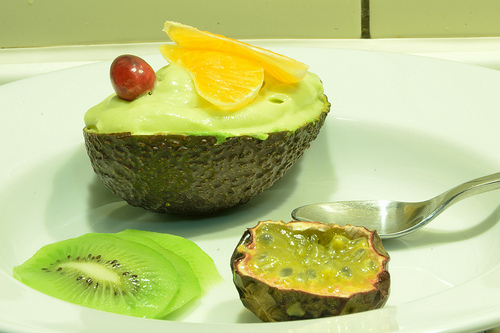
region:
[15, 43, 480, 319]
fruits arranged in a plate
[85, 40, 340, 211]
avocado half topped with fruit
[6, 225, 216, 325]
slices of overlapping kiwi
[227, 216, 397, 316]
cut fruit with thick skin and gooey interior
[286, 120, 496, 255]
silver spoon placed in a plate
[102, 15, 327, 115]
grape and orange segments on filled avocado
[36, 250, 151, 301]
black seeds in an oval shape around white center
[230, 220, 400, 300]
dark seeds in juicy opaque filling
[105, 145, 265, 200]
bumpy texture of avocado peel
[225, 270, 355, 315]
mottled skin covering fruit in earthy tones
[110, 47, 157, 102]
a single olive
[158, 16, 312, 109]
two orange slices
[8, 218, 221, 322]
three kiwi slices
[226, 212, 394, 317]
half of a mushy green fruit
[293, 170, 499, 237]
a silver spoon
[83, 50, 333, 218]
half of a baked avocado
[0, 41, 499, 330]
a dish of assorted fruit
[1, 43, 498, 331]
the bowl is white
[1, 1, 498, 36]
the wall is made of large tiles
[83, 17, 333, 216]
fruit is perched on an avocado half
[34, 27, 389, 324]
Fruit on a plate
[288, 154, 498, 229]
A spoon on the plate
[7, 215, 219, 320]
Slices of kiwi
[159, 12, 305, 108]
Oranges on top of fruit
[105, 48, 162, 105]
Grapes on top of fruit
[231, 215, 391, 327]
A rotting kiwi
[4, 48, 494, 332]
A plate full of fruit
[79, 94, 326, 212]
A half of a fruit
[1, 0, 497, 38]
A wall behind a plate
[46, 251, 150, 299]
Seeds in the kiwi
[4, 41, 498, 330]
a white bowl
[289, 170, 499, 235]
a teaspoon is in the white bowl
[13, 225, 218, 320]
there are pieces of kiwi in the bowl.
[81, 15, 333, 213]
there is an avocado in the bowl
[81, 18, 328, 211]
the avocado has been cut in half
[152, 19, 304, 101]
there are two orange slices on top of the avocado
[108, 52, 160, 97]
a red cherry is next to the orange slices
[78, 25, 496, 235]
The spoon is next to the avocado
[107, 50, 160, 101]
the cherry is on top of the avocado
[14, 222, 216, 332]
The kiwi slices are next to the avocado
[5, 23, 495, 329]
Fruit on a plate.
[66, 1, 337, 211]
An avocado skin filled with whipped avocado.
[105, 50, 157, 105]
A red grape.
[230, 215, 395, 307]
Passion fruit.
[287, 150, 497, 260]
A spoon made from stainless steel.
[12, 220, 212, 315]
Three slices of kiwi.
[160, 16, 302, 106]
Two orange segments.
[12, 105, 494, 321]
The plate has a depression in the center.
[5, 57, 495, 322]
The plate is white.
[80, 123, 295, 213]
The avocado skin is green and bumpy.